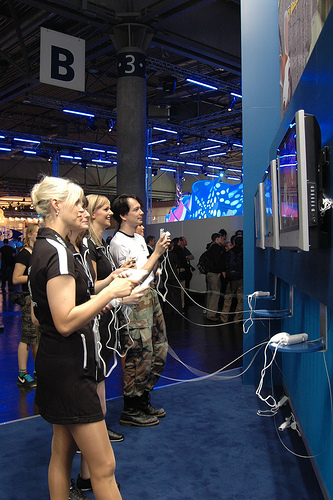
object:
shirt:
[108, 229, 156, 294]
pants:
[122, 286, 169, 396]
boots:
[120, 395, 166, 428]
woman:
[12, 223, 48, 389]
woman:
[28, 176, 131, 500]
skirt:
[37, 332, 106, 425]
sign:
[37, 24, 87, 92]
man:
[106, 194, 168, 427]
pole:
[111, 19, 150, 234]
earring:
[56, 209, 60, 218]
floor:
[2, 254, 311, 458]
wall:
[255, 10, 333, 500]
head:
[24, 223, 41, 248]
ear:
[50, 197, 61, 211]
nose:
[78, 207, 86, 215]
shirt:
[12, 248, 37, 299]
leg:
[48, 423, 79, 500]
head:
[111, 192, 144, 235]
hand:
[108, 277, 134, 299]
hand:
[153, 235, 171, 254]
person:
[76, 193, 137, 441]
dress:
[28, 227, 105, 426]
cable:
[162, 240, 285, 329]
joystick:
[165, 229, 172, 239]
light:
[185, 76, 220, 92]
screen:
[275, 110, 331, 255]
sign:
[164, 179, 247, 222]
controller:
[278, 332, 310, 346]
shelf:
[271, 329, 324, 354]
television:
[260, 159, 281, 252]